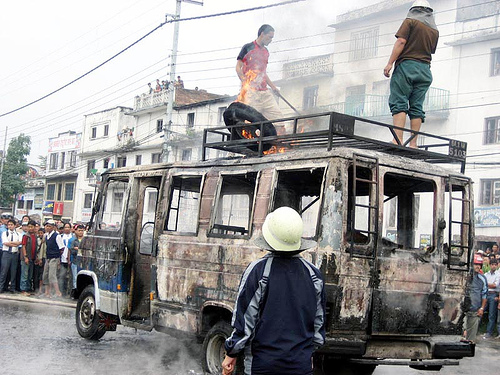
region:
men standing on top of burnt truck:
[70, 1, 476, 367]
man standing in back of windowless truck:
[216, 197, 331, 367]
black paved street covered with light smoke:
[5, 286, 211, 371]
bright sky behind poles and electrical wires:
[5, 0, 330, 160]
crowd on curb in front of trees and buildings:
[0, 127, 80, 304]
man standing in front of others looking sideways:
[465, 241, 495, 341]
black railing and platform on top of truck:
[200, 110, 467, 171]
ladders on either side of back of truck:
[345, 151, 470, 271]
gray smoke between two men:
[230, 0, 435, 155]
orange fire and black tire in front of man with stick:
[225, 22, 296, 153]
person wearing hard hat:
[214, 203, 345, 373]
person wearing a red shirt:
[227, 9, 299, 155]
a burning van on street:
[67, 94, 490, 373]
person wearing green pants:
[382, 0, 454, 155]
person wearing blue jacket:
[214, 204, 339, 371]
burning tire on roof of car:
[219, 89, 285, 154]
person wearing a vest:
[18, 219, 43, 291]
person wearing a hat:
[37, 219, 66, 300]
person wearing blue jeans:
[15, 220, 45, 300]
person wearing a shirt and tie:
[0, 219, 28, 287]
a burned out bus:
[67, 113, 476, 374]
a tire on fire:
[224, 70, 301, 151]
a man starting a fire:
[220, 20, 308, 155]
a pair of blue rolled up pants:
[390, 58, 431, 120]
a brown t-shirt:
[395, 14, 438, 63]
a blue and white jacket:
[224, 252, 326, 364]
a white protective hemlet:
[261, 205, 303, 254]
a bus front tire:
[75, 287, 107, 342]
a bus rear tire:
[199, 322, 231, 373]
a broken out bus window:
[210, 173, 254, 236]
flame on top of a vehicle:
[230, 69, 286, 155]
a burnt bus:
[61, 119, 486, 374]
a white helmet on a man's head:
[257, 206, 311, 255]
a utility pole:
[164, 0, 192, 86]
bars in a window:
[348, 25, 384, 61]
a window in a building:
[485, 116, 499, 145]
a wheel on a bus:
[73, 284, 108, 343]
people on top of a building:
[145, 74, 186, 90]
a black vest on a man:
[39, 231, 61, 261]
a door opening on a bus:
[116, 164, 171, 324]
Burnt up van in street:
[30, 118, 473, 371]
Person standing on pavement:
[218, 207, 340, 372]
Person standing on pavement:
[490, 265, 499, 287]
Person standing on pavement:
[65, 217, 90, 313]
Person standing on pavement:
[38, 212, 75, 294]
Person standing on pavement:
[20, 211, 41, 319]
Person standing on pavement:
[2, 217, 22, 295]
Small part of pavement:
[10, 346, 30, 373]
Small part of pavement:
[56, 333, 118, 372]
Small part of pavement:
[139, 338, 182, 371]